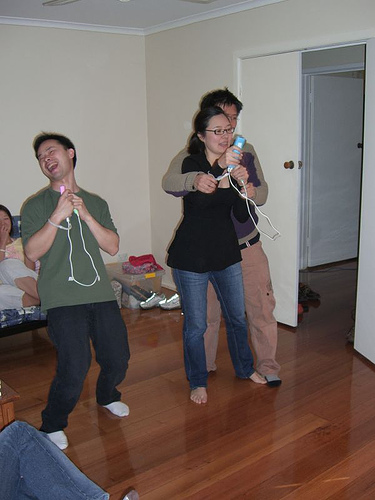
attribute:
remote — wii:
[229, 136, 247, 172]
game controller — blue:
[224, 132, 247, 171]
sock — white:
[123, 489, 139, 499]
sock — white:
[101, 401, 129, 417]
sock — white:
[46, 430, 67, 448]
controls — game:
[217, 129, 247, 179]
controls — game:
[56, 179, 79, 224]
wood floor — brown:
[159, 410, 352, 474]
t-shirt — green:
[20, 187, 117, 311]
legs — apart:
[165, 241, 281, 418]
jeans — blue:
[161, 257, 260, 387]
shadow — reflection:
[83, 401, 153, 499]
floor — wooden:
[119, 380, 302, 495]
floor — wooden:
[307, 359, 355, 429]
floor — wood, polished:
[182, 389, 360, 488]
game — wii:
[215, 132, 293, 247]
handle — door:
[281, 156, 308, 172]